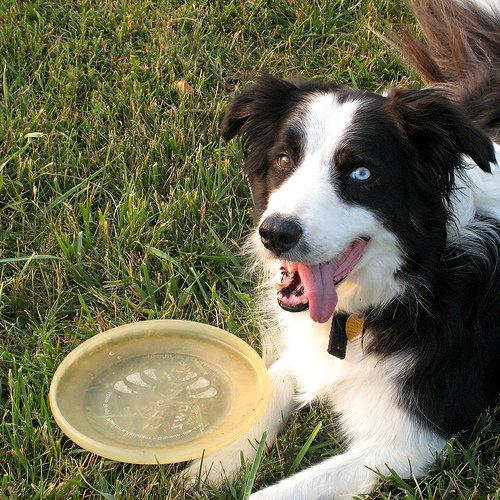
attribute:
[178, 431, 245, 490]
paw — white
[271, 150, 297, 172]
eye — brown, blue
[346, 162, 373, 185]
eye — brown, blue